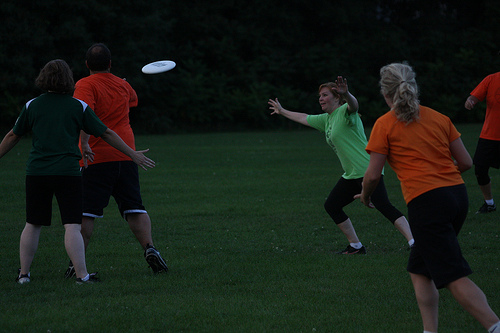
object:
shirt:
[364, 103, 466, 204]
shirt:
[306, 101, 386, 179]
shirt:
[13, 91, 107, 177]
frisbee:
[140, 59, 177, 74]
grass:
[0, 122, 499, 332]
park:
[0, 0, 499, 332]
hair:
[380, 61, 419, 126]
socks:
[350, 242, 365, 249]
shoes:
[142, 243, 169, 274]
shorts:
[407, 182, 474, 290]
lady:
[360, 60, 500, 332]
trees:
[0, 1, 499, 137]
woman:
[267, 74, 415, 257]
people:
[0, 58, 158, 286]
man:
[65, 43, 169, 279]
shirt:
[72, 74, 139, 167]